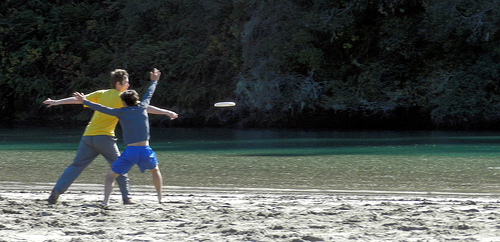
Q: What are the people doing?
A: Frisbee.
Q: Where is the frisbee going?
A: Water.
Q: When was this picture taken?
A: Daytime.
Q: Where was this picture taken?
A: Beach.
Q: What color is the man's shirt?
A: Yellow.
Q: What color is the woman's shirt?
A: Blue.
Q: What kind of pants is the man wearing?
A: Jeans.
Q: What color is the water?
A: Blue.